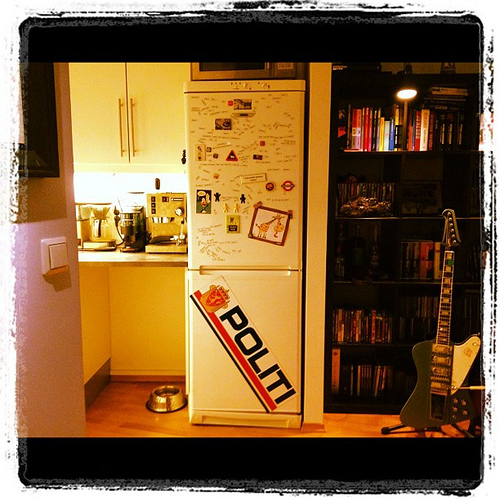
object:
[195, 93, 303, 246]
magnets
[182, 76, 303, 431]
refrigerator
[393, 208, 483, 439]
guitar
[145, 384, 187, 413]
dish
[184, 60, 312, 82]
microwave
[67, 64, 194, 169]
cabinet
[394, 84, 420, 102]
light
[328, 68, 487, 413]
bookshelf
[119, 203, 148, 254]
coffee pot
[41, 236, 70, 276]
thermastat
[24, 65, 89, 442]
wall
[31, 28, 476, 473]
kitchen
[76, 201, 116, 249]
appliances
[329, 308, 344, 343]
books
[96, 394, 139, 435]
floor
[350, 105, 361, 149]
book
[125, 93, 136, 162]
handle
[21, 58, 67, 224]
picture